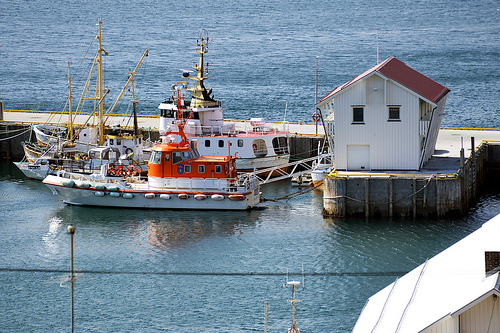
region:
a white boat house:
[301, 39, 432, 179]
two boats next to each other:
[25, 60, 300, 244]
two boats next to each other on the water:
[54, 28, 367, 275]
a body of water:
[38, 232, 410, 330]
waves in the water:
[55, 28, 322, 94]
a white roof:
[315, 243, 472, 330]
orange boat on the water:
[43, 119, 298, 221]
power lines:
[19, 238, 406, 298]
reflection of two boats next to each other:
[38, 209, 302, 269]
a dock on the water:
[20, 53, 491, 188]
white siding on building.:
[382, 138, 404, 158]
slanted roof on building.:
[437, 255, 464, 289]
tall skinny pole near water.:
[64, 233, 77, 315]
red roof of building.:
[399, 68, 426, 90]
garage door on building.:
[349, 147, 368, 167]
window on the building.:
[352, 107, 363, 126]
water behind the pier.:
[247, 32, 304, 74]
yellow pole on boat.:
[98, 58, 103, 130]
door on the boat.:
[163, 153, 173, 175]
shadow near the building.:
[439, 155, 460, 172]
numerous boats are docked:
[27, 115, 282, 235]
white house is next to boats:
[318, 53, 452, 171]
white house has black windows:
[346, 88, 419, 158]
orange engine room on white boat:
[133, 102, 243, 194]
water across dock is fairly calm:
[120, 22, 306, 125]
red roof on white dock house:
[317, 44, 430, 106]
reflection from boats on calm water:
[57, 188, 264, 252]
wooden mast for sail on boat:
[57, 35, 124, 136]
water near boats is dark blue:
[70, 227, 283, 319]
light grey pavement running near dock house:
[30, 102, 476, 166]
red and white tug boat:
[39, 143, 266, 219]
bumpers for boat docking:
[65, 175, 248, 202]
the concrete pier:
[0, 101, 497, 144]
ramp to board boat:
[235, 151, 347, 186]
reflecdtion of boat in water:
[38, 211, 281, 288]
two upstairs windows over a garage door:
[343, 100, 416, 170]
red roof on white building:
[312, 52, 457, 102]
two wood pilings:
[452, 125, 484, 225]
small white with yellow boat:
[308, 116, 333, 206]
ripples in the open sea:
[3, 1, 499, 116]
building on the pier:
[319, 71, 433, 169]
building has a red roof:
[327, 64, 436, 95]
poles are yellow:
[61, 46, 112, 128]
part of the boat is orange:
[151, 145, 241, 180]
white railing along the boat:
[131, 174, 219, 193]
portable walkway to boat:
[239, 150, 341, 178]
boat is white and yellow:
[310, 167, 324, 191]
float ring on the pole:
[305, 105, 330, 125]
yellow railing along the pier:
[347, 166, 449, 184]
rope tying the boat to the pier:
[260, 175, 340, 200]